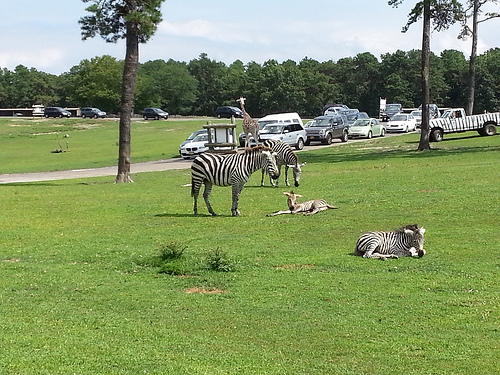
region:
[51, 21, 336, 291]
these are zebras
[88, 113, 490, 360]
the animals are captive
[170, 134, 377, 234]
the zebras are grazing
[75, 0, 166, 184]
a tree in a park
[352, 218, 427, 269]
a zebra on the ground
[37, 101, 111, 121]
two cars on the road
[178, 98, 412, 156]
cars parked in a line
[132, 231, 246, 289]
small patches of plants on grass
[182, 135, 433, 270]
a pack of animals in a park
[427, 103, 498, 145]
a trick painted like a zebra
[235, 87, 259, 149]
a giraffe walking in a park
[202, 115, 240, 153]
a small wooden sign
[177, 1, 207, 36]
white clouds in blue sky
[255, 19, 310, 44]
white clouds in blue sky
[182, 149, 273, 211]
black and white striped zebra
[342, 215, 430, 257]
black and white striped zebra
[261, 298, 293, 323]
short green and yellow grass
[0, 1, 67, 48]
white clouds in blue sky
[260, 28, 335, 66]
white clouds in blue sky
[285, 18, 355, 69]
white clouds in blue sky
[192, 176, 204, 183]
black stripe on zebra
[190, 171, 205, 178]
black stripe on zebra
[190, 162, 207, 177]
black stripe on zebra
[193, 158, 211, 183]
black stripe on zebra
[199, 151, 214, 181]
black stripe on zebra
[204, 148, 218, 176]
black stripe on zebra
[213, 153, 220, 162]
black stripe on zebra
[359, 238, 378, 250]
black stripe on zebra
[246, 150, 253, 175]
black stripe on zebra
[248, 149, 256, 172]
black stripe on zebra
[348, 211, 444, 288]
zebra on the ground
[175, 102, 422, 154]
cars at the narrow street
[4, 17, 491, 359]
cars driving through outdoor zoo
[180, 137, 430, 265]
standing adult zebras behind lying young zebras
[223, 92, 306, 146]
giraffe crossing in front of car with twisted head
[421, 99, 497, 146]
truck painted in zebra stripes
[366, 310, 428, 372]
the lawn is green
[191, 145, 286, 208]
a zebra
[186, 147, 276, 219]
a zebra in grass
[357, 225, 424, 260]
a zebra in grass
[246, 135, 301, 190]
a zebra in grass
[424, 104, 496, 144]
a zebra striped truck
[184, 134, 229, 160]
a parked car on a path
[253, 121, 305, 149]
a parked car on a path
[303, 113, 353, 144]
a parked car on a path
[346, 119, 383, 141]
a parked car on a path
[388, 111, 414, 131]
a parked car on a path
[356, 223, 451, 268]
zebra laying in the grass